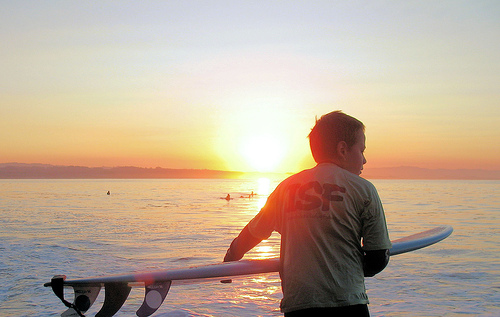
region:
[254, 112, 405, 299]
young boy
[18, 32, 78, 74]
blue sky with no clouds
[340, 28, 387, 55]
blue sky with no clouds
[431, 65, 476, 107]
blue sky with no clouds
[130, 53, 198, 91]
blue sky with no clouds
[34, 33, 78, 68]
blue sky with no clouds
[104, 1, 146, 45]
blue sky with no clouds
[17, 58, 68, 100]
blue sky with no clouds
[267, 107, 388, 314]
this is a boy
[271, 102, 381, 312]
the boy is walking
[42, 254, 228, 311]
this is a surf board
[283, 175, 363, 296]
this is at shirt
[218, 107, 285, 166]
the sun is setting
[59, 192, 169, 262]
this is the water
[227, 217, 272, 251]
this is the hand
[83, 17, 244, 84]
this is the sky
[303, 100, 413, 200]
face of the person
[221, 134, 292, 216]
a sun in the sky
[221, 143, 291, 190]
a sun near to water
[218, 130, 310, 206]
a sun in side the water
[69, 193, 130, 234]
riddles on the water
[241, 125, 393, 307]
a man wearing shirt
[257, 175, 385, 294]
a boy wearing t shirt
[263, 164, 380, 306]
the tshirt is grey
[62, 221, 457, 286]
the surfboard is white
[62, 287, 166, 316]
the fins are three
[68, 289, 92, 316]
the fin is white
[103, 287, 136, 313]
the fin is black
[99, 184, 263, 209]
the poeple are in the water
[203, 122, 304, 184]
the sun is in the backround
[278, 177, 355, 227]
isf letters are on the shirt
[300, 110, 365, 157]
the hair is brown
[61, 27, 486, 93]
the sky is cloudless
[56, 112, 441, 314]
person and surfboard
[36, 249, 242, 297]
left hand holding board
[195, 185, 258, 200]
people in the water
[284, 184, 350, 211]
big letters on back of shirt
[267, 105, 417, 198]
person looking to the right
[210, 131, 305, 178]
sun setting in the back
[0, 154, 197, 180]
mountains in the distance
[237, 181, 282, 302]
reflection on the water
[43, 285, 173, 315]
three objects under the board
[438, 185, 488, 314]
ripples in the water